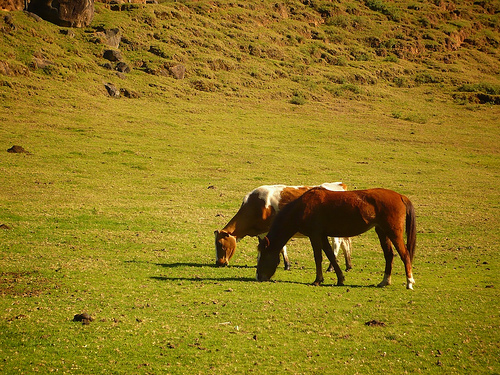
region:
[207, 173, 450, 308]
Multiple animals grazing in a field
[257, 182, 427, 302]
A brown horse standing by a cow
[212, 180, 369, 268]
A white and brown cow standing by a horse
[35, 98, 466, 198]
Short green grass grows in the field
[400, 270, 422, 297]
A white hoof on the horse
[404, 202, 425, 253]
A drooping brown horse tail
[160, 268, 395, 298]
The black shadow of the horse on the ground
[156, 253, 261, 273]
The shadow of the cow in the grass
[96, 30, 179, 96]
A rocky outcropping on the hill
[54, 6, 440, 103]
A large grassy hill behind the animals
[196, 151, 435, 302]
a horse and a cow in the field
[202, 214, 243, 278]
the cow eating the grass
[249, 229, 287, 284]
the horse eating in the grass field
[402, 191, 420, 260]
the brown hair of the horses tail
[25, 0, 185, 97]
rocka and boulders on the hillside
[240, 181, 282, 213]
the white patches on the brown cow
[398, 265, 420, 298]
the white part of the horses foot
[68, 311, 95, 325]
clumps of dirt in the grass field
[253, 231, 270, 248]
the ears of the horse pokeing up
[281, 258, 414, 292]
the legs of the animals on the gorund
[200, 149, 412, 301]
two animals grazing in field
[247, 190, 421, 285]
brown horse grazing in field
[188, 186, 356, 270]
brown and white cow grazing in field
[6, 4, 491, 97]
grass covered hillside behind animals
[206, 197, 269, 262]
brown neck and face of cow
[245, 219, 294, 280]
brown neck and face of horse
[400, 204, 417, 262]
brown tail of horse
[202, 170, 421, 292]
horse and cow standing side by side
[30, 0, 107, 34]
large rock on hillside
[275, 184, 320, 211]
brown spot on cow's side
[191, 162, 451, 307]
Multiple species of animal grazing in a field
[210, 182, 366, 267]
A brown and white cow standing by a horse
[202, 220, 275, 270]
The cow is grazing on the grass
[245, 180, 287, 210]
A large white spot on the cow's body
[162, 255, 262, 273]
Shadow of the cow in the grass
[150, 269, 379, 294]
Black shadow of the horse on the ground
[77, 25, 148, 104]
A rocky outcropping on the hill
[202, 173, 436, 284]
two animals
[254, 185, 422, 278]
a brown horse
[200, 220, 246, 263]
a cow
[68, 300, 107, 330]
rocks on the grass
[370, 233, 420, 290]
the horses back legs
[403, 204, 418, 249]
the horses brown tail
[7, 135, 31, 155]
a rock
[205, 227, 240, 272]
the cow is eating grass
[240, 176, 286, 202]
the cow is brown and white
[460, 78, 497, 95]
a patch of grass